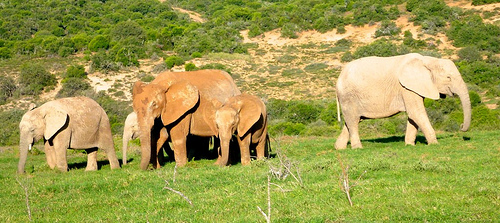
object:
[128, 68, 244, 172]
elephant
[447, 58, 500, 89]
branches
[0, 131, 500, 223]
ground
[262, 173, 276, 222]
stick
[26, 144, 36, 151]
tusk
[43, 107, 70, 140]
ear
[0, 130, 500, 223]
green grass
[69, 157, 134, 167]
shadows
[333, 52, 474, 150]
elephant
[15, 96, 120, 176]
elephant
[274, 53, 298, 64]
grass patch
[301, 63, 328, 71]
grass patch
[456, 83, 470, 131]
trunk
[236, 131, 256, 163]
leg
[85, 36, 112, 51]
bush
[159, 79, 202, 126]
ear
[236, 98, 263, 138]
ear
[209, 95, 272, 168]
elephant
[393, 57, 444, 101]
ear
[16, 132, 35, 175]
trunk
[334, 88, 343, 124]
tail